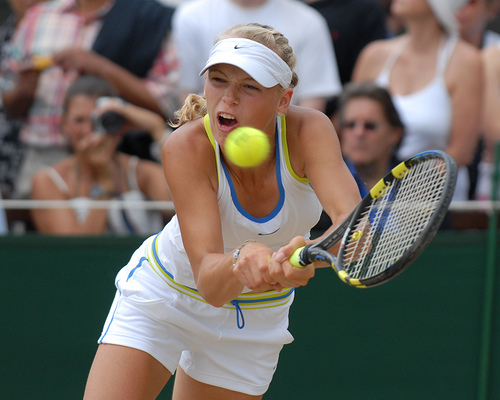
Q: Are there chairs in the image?
A: No, there are no chairs.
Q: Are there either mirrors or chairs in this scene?
A: No, there are no chairs or mirrors.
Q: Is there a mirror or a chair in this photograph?
A: No, there are no chairs or mirrors.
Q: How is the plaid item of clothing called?
A: The clothing item is a shirt.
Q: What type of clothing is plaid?
A: The clothing is a shirt.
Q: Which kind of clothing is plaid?
A: The clothing is a shirt.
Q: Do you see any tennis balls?
A: Yes, there is a tennis ball.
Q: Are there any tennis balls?
A: Yes, there is a tennis ball.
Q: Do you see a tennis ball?
A: Yes, there is a tennis ball.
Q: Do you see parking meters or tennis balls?
A: Yes, there is a tennis ball.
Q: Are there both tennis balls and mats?
A: No, there is a tennis ball but no mats.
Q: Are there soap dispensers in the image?
A: No, there are no soap dispensers.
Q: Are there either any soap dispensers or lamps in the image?
A: No, there are no soap dispensers or lamps.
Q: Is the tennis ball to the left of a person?
A: No, the tennis ball is to the right of a person.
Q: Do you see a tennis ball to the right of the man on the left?
A: Yes, there is a tennis ball to the right of the man.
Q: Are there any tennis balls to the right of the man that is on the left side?
A: Yes, there is a tennis ball to the right of the man.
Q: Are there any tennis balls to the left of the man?
A: No, the tennis ball is to the right of the man.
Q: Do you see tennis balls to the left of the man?
A: No, the tennis ball is to the right of the man.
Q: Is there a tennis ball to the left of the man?
A: No, the tennis ball is to the right of the man.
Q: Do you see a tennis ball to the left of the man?
A: No, the tennis ball is to the right of the man.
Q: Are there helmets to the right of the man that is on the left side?
A: No, there is a tennis ball to the right of the man.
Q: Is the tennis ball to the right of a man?
A: Yes, the tennis ball is to the right of a man.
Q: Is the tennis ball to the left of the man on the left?
A: No, the tennis ball is to the right of the man.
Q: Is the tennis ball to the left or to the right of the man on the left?
A: The tennis ball is to the right of the man.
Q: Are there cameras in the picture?
A: Yes, there is a camera.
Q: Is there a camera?
A: Yes, there is a camera.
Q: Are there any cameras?
A: Yes, there is a camera.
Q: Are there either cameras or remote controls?
A: Yes, there is a camera.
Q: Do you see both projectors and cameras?
A: No, there is a camera but no projectors.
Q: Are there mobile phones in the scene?
A: No, there are no mobile phones.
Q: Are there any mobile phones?
A: No, there are no mobile phones.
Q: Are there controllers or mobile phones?
A: No, there are no mobile phones or controllers.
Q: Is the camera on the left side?
A: Yes, the camera is on the left of the image.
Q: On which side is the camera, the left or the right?
A: The camera is on the left of the image.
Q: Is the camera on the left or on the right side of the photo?
A: The camera is on the left of the image.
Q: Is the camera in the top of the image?
A: Yes, the camera is in the top of the image.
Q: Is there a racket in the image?
A: Yes, there is a racket.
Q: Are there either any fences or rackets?
A: Yes, there is a racket.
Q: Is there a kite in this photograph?
A: No, there are no kites.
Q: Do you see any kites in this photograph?
A: No, there are no kites.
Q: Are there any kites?
A: No, there are no kites.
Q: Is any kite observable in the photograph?
A: No, there are no kites.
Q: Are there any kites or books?
A: No, there are no kites or books.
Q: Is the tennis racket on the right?
A: Yes, the tennis racket is on the right of the image.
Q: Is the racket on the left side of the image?
A: No, the racket is on the right of the image.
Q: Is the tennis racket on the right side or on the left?
A: The tennis racket is on the right of the image.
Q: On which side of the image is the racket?
A: The racket is on the right of the image.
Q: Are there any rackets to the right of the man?
A: Yes, there is a racket to the right of the man.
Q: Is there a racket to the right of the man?
A: Yes, there is a racket to the right of the man.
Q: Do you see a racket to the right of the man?
A: Yes, there is a racket to the right of the man.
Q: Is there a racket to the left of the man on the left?
A: No, the racket is to the right of the man.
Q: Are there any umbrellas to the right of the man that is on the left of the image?
A: No, there is a racket to the right of the man.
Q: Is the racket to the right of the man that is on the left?
A: Yes, the racket is to the right of the man.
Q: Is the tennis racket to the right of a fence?
A: No, the tennis racket is to the right of the man.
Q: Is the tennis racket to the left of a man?
A: No, the tennis racket is to the right of a man.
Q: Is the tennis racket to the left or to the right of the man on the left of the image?
A: The tennis racket is to the right of the man.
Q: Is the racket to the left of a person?
A: No, the racket is to the right of a person.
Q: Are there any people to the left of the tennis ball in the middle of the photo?
A: Yes, there is a person to the left of the tennis ball.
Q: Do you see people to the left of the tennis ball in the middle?
A: Yes, there is a person to the left of the tennis ball.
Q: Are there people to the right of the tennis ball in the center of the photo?
A: No, the person is to the left of the tennis ball.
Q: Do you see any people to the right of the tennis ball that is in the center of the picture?
A: No, the person is to the left of the tennis ball.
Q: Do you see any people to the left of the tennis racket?
A: Yes, there is a person to the left of the tennis racket.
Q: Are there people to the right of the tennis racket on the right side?
A: No, the person is to the left of the tennis racket.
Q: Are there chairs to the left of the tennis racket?
A: No, there is a person to the left of the tennis racket.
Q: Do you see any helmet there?
A: No, there are no helmets.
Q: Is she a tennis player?
A: Yes, this is a tennis player.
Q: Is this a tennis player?
A: Yes, this is a tennis player.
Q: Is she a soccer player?
A: No, this is a tennis player.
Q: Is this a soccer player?
A: No, this is a tennis player.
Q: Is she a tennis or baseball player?
A: This is a tennis player.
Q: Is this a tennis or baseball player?
A: This is a tennis player.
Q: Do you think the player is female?
A: Yes, the player is female.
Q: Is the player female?
A: Yes, the player is female.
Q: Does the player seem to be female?
A: Yes, the player is female.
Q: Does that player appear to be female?
A: Yes, the player is female.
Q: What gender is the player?
A: The player is female.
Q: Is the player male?
A: No, the player is female.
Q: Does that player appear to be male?
A: No, the player is female.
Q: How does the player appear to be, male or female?
A: The player is female.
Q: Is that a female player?
A: Yes, that is a female player.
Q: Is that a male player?
A: No, that is a female player.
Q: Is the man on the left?
A: Yes, the man is on the left of the image.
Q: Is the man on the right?
A: No, the man is on the left of the image.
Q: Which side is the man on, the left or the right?
A: The man is on the left of the image.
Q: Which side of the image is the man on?
A: The man is on the left of the image.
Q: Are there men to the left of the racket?
A: Yes, there is a man to the left of the racket.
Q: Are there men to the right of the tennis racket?
A: No, the man is to the left of the tennis racket.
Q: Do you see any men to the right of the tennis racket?
A: No, the man is to the left of the tennis racket.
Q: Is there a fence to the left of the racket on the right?
A: No, there is a man to the left of the racket.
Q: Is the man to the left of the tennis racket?
A: Yes, the man is to the left of the tennis racket.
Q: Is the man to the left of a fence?
A: No, the man is to the left of the tennis racket.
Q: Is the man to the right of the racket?
A: No, the man is to the left of the racket.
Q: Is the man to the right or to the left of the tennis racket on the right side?
A: The man is to the left of the tennis racket.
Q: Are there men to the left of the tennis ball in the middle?
A: Yes, there is a man to the left of the tennis ball.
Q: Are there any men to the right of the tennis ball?
A: No, the man is to the left of the tennis ball.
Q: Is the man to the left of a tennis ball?
A: Yes, the man is to the left of a tennis ball.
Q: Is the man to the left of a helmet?
A: No, the man is to the left of a tennis ball.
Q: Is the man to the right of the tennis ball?
A: No, the man is to the left of the tennis ball.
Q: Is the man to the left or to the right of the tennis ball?
A: The man is to the left of the tennis ball.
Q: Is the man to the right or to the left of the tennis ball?
A: The man is to the left of the tennis ball.